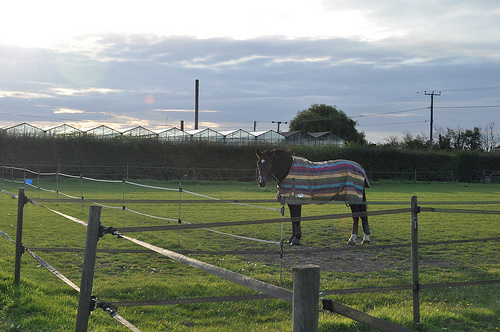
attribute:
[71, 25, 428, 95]
clouds — white 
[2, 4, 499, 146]
sky — blue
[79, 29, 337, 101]
clouds — white